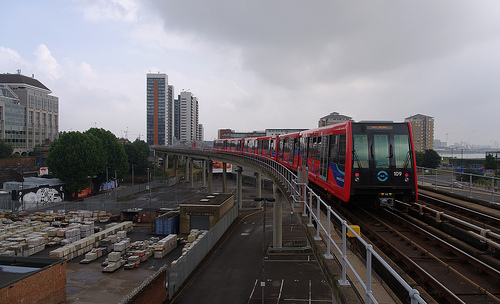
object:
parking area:
[172, 205, 336, 304]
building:
[144, 73, 174, 147]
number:
[391, 168, 404, 178]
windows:
[156, 112, 166, 116]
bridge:
[152, 134, 500, 304]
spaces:
[264, 248, 312, 262]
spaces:
[310, 276, 334, 300]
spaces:
[282, 279, 311, 298]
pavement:
[126, 172, 338, 303]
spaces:
[250, 274, 281, 300]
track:
[152, 146, 500, 304]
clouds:
[0, 1, 498, 154]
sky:
[3, 5, 500, 148]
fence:
[162, 144, 499, 304]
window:
[351, 131, 422, 170]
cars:
[121, 253, 144, 271]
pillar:
[269, 184, 284, 251]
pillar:
[252, 167, 265, 212]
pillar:
[218, 162, 232, 194]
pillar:
[186, 153, 197, 190]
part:
[337, 135, 346, 162]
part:
[272, 206, 280, 224]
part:
[352, 134, 372, 170]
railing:
[306, 196, 326, 244]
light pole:
[259, 203, 272, 250]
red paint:
[209, 121, 419, 198]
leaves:
[67, 148, 99, 169]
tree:
[47, 129, 110, 196]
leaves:
[89, 146, 112, 164]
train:
[213, 120, 417, 201]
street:
[8, 174, 303, 304]